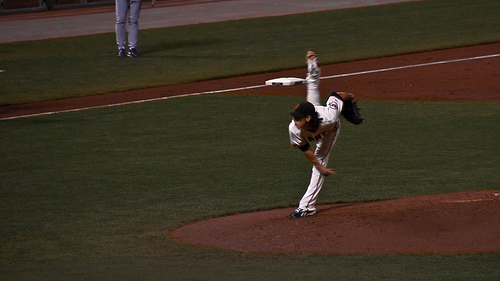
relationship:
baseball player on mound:
[285, 49, 366, 218] [171, 191, 500, 259]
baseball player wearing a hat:
[285, 49, 366, 218] [288, 101, 315, 117]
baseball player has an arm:
[285, 49, 366, 218] [287, 125, 336, 176]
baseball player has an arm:
[285, 49, 366, 218] [327, 88, 359, 119]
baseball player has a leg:
[285, 49, 366, 218] [289, 135, 342, 216]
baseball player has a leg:
[285, 49, 366, 218] [305, 48, 321, 109]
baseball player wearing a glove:
[285, 49, 366, 218] [342, 100, 365, 124]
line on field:
[0, 51, 500, 128] [0, 0, 497, 280]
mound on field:
[171, 191, 500, 259] [0, 0, 497, 280]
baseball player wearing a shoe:
[285, 49, 366, 218] [292, 209, 317, 217]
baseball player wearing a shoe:
[285, 49, 366, 218] [307, 49, 318, 76]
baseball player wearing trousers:
[285, 49, 366, 218] [297, 129, 340, 210]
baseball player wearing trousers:
[285, 49, 366, 218] [308, 75, 321, 104]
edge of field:
[1, 6, 395, 41] [0, 0, 497, 280]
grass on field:
[1, 94, 497, 200] [0, 0, 497, 280]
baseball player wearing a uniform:
[285, 49, 366, 218] [286, 72, 344, 206]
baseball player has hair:
[285, 49, 366, 218] [310, 109, 322, 130]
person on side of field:
[111, 1, 141, 58] [0, 0, 497, 280]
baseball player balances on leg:
[285, 49, 366, 218] [289, 135, 342, 216]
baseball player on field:
[285, 49, 366, 218] [0, 0, 497, 280]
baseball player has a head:
[285, 49, 366, 218] [288, 102, 324, 129]